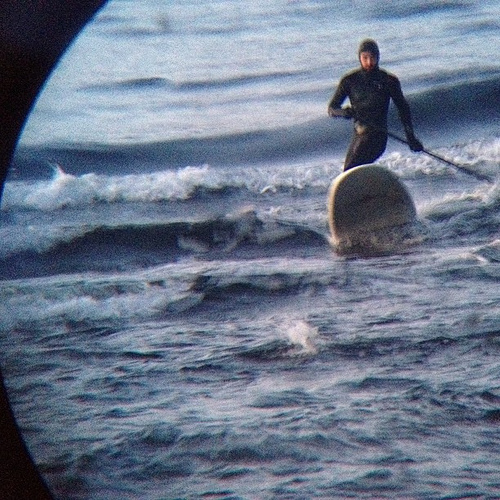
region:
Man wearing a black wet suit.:
[325, 31, 426, 173]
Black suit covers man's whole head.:
[350, 35, 392, 70]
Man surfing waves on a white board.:
[307, 151, 426, 253]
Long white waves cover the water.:
[5, 147, 499, 249]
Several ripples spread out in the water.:
[5, 280, 497, 498]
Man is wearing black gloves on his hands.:
[402, 137, 424, 157]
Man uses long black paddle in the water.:
[338, 102, 498, 202]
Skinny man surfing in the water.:
[324, 25, 428, 172]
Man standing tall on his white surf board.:
[302, 25, 495, 261]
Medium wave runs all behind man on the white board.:
[22, 64, 496, 179]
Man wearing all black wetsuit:
[326, 38, 421, 171]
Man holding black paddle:
[325, 38, 425, 171]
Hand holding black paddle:
[405, 135, 425, 150]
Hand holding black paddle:
[345, 107, 362, 119]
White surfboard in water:
[324, 164, 415, 245]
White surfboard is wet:
[325, 160, 415, 241]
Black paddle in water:
[353, 113, 493, 187]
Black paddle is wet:
[361, 110, 488, 187]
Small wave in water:
[27, 163, 223, 198]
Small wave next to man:
[5, 213, 275, 266]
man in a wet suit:
[329, 38, 421, 176]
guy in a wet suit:
[328, 38, 423, 170]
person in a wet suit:
[327, 38, 424, 173]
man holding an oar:
[326, 39, 423, 191]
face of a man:
[359, 52, 378, 69]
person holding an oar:
[326, 38, 422, 179]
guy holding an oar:
[325, 38, 491, 183]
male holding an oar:
[325, 38, 493, 184]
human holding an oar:
[325, 38, 488, 179]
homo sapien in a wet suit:
[329, 39, 424, 179]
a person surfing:
[192, 8, 447, 326]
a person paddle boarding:
[271, 32, 498, 373]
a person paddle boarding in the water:
[297, 12, 489, 222]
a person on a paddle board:
[258, 20, 485, 350]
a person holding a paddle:
[257, 8, 499, 305]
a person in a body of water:
[203, 9, 489, 229]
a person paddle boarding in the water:
[132, 8, 499, 345]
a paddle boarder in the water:
[177, 16, 498, 343]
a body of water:
[101, 18, 493, 499]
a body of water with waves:
[40, 3, 499, 496]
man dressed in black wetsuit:
[327, 37, 426, 182]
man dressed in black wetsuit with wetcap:
[328, 39, 428, 179]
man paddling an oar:
[325, 39, 424, 179]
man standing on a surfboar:
[324, 37, 416, 170]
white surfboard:
[326, 162, 420, 246]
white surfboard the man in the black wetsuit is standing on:
[321, 161, 418, 231]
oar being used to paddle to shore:
[356, 114, 496, 190]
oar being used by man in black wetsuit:
[360, 112, 490, 187]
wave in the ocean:
[6, 139, 498, 206]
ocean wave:
[1, 206, 327, 258]